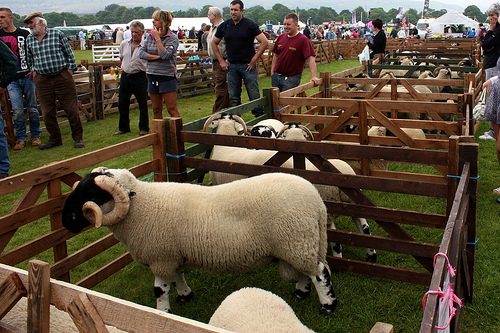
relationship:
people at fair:
[1, 1, 500, 203] [0, 0, 499, 332]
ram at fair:
[61, 167, 337, 315] [0, 0, 499, 332]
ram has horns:
[61, 167, 337, 315] [72, 165, 131, 228]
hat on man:
[23, 12, 46, 23] [23, 12, 83, 150]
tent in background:
[20, 16, 214, 32] [0, 0, 499, 44]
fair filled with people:
[0, 0, 499, 332] [1, 1, 500, 203]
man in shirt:
[270, 13, 322, 90] [273, 31, 316, 75]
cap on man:
[23, 12, 46, 23] [23, 12, 83, 150]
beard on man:
[30, 20, 41, 37] [23, 12, 83, 150]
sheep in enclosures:
[0, 42, 473, 329] [0, 38, 486, 332]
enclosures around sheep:
[0, 38, 486, 332] [0, 42, 473, 329]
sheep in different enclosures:
[0, 42, 473, 329] [0, 38, 486, 332]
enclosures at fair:
[0, 38, 486, 332] [0, 0, 499, 332]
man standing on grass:
[23, 12, 83, 150] [0, 49, 499, 332]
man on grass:
[23, 12, 83, 150] [0, 49, 499, 332]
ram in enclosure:
[61, 167, 337, 315] [1, 119, 479, 332]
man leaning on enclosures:
[23, 12, 83, 150] [0, 38, 486, 332]